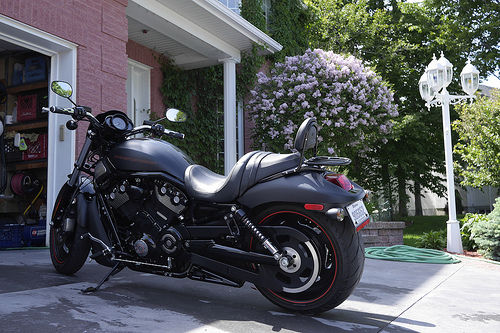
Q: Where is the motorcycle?
A: In the driveway.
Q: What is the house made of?
A: Brick.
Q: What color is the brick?
A: Red.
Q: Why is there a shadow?
A: The sun is behind the house.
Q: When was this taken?
A: During the day.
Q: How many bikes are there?
A: One.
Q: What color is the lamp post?
A: White.